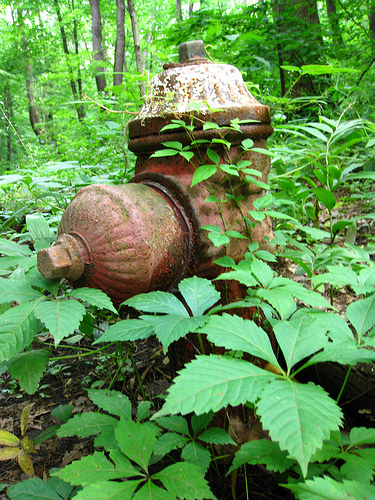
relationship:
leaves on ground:
[3, 409, 39, 477] [28, 377, 104, 450]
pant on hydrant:
[141, 64, 253, 114] [25, 28, 288, 339]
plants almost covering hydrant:
[3, 267, 323, 457] [38, 41, 281, 288]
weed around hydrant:
[0, 212, 375, 499] [36, 40, 279, 321]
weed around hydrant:
[0, 266, 117, 357] [36, 40, 279, 321]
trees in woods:
[0, 0, 373, 188] [0, 0, 375, 498]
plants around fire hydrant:
[91, 254, 374, 479] [14, 42, 312, 406]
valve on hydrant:
[15, 200, 179, 297] [26, 45, 311, 332]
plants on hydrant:
[91, 254, 374, 479] [39, 25, 321, 453]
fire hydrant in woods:
[36, 39, 284, 374] [0, 0, 372, 200]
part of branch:
[118, 110, 136, 114] [77, 93, 149, 126]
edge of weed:
[206, 414, 227, 436] [0, 212, 375, 499]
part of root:
[223, 420, 242, 444] [216, 452, 244, 486]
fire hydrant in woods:
[36, 39, 284, 374] [2, 1, 373, 499]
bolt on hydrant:
[36, 242, 70, 281] [37, 37, 275, 377]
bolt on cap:
[36, 242, 70, 281] [33, 181, 186, 300]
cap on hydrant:
[33, 181, 186, 300] [37, 37, 275, 377]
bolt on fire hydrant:
[167, 30, 211, 63] [44, 36, 293, 291]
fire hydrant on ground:
[36, 32, 324, 288] [55, 371, 109, 406]